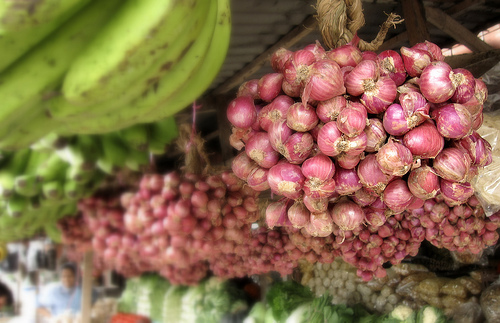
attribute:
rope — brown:
[312, 0, 399, 52]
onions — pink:
[61, 47, 498, 284]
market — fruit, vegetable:
[0, 1, 493, 321]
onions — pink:
[223, 28, 493, 238]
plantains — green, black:
[3, 3, 230, 151]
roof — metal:
[226, 17, 278, 38]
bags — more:
[131, 279, 320, 318]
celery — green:
[112, 272, 445, 321]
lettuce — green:
[114, 270, 450, 321]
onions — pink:
[313, 57, 475, 177]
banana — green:
[41, 7, 228, 126]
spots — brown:
[84, 36, 183, 101]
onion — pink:
[428, 104, 478, 145]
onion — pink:
[415, 59, 467, 102]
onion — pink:
[345, 54, 381, 99]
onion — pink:
[329, 104, 370, 134]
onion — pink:
[353, 154, 391, 193]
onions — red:
[228, 40, 497, 250]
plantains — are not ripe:
[30, 1, 239, 149]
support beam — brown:
[432, 10, 489, 53]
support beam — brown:
[399, 0, 430, 42]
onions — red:
[214, 22, 495, 253]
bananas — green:
[0, 5, 233, 128]